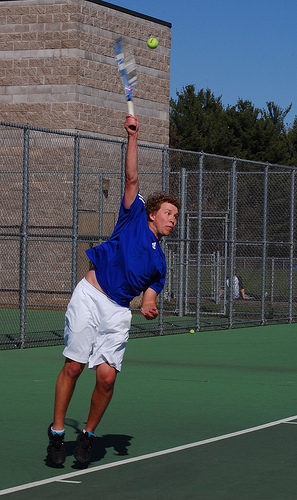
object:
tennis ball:
[147, 37, 159, 49]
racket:
[114, 35, 139, 129]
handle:
[127, 99, 136, 130]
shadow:
[45, 418, 131, 472]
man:
[44, 114, 181, 466]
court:
[0, 302, 294, 500]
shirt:
[84, 186, 166, 308]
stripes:
[138, 191, 145, 203]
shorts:
[63, 276, 133, 373]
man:
[218, 265, 267, 302]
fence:
[0, 120, 296, 351]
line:
[0, 414, 291, 494]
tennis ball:
[190, 329, 195, 334]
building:
[0, 1, 172, 308]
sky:
[112, 0, 297, 87]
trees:
[167, 82, 295, 254]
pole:
[19, 127, 29, 350]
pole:
[70, 132, 80, 297]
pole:
[195, 150, 204, 334]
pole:
[228, 159, 238, 329]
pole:
[260, 161, 268, 324]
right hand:
[124, 113, 139, 135]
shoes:
[46, 422, 67, 467]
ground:
[10, 353, 295, 495]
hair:
[145, 190, 181, 221]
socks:
[50, 426, 65, 436]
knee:
[98, 368, 119, 392]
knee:
[67, 360, 82, 379]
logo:
[151, 240, 157, 250]